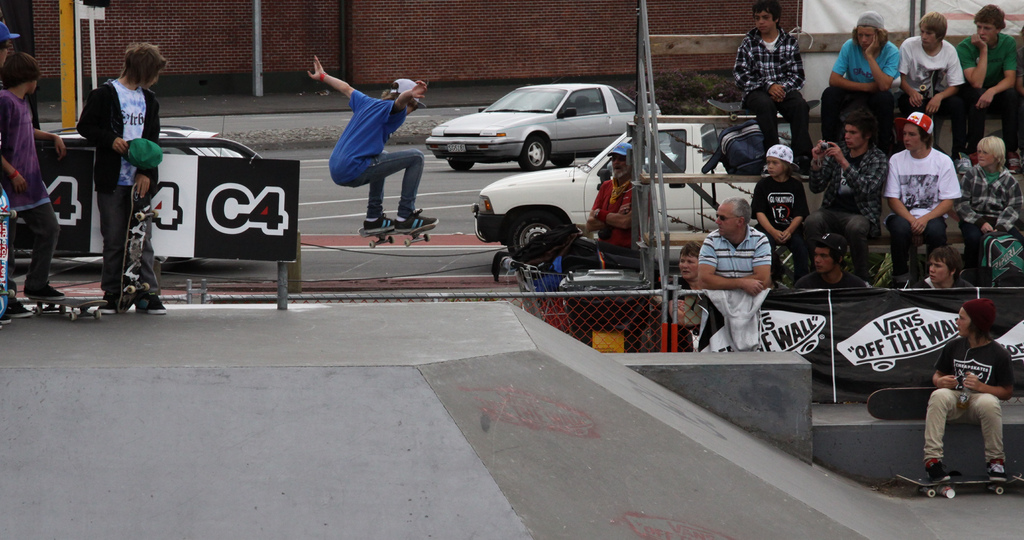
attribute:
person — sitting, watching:
[910, 288, 1021, 503]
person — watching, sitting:
[904, 247, 982, 314]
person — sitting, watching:
[793, 232, 843, 293]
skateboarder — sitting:
[292, 52, 480, 266]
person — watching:
[670, 188, 798, 359]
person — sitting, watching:
[670, 242, 703, 309]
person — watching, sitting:
[794, 104, 903, 264]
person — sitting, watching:
[878, 108, 971, 277]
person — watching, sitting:
[940, 113, 1021, 276]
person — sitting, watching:
[754, 124, 815, 282]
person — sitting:
[832, 121, 895, 260]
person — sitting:
[893, 93, 967, 271]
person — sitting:
[955, 9, 1022, 120]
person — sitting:
[889, 9, 967, 130]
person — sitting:
[821, 14, 901, 135]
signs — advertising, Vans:
[750, 297, 984, 399]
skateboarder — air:
[296, 42, 448, 252]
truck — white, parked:
[458, 109, 794, 235]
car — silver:
[413, 54, 681, 160]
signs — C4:
[44, 132, 336, 293]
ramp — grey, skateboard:
[1, 316, 1021, 537]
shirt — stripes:
[688, 236, 782, 286]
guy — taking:
[806, 119, 887, 193]